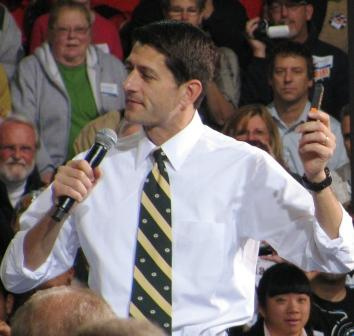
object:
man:
[1, 19, 354, 329]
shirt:
[0, 109, 354, 336]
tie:
[128, 150, 173, 336]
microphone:
[51, 127, 118, 223]